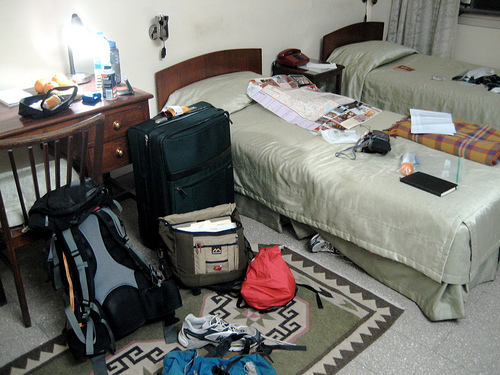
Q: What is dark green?
A: The suitcase.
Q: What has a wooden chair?
A: The brown desk.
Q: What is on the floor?
A: A rug is on it.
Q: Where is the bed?
A: Next to the window.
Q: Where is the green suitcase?
A: Next to the bed.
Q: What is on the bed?
A: A map.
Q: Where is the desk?
A: Next to the chair.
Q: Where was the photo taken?
A: In a bedroom.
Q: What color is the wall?
A: White.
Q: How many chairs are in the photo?
A: One.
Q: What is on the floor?
A: A rug.